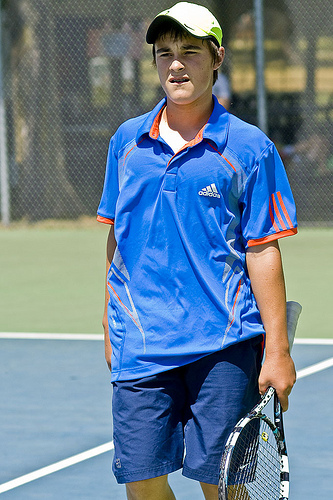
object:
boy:
[96, 0, 298, 497]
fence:
[0, 0, 333, 229]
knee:
[126, 461, 168, 500]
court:
[0, 0, 333, 500]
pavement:
[0, 333, 333, 497]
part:
[246, 239, 297, 413]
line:
[0, 440, 114, 495]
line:
[0, 332, 104, 340]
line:
[299, 358, 320, 382]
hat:
[145, 1, 223, 48]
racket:
[217, 301, 303, 499]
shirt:
[96, 95, 299, 385]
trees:
[265, 0, 333, 107]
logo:
[198, 183, 220, 199]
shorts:
[112, 333, 266, 487]